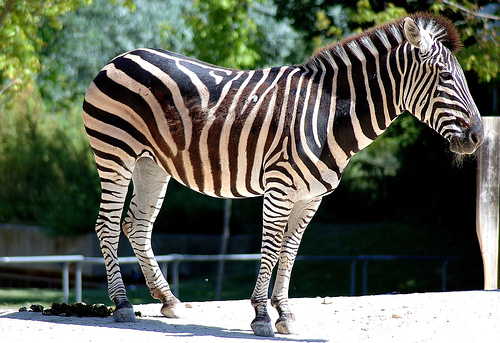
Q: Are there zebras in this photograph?
A: Yes, there is a zebra.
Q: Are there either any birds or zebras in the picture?
A: Yes, there is a zebra.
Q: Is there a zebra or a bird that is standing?
A: Yes, the zebra is standing.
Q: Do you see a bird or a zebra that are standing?
A: Yes, the zebra is standing.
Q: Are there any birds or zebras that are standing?
A: Yes, the zebra is standing.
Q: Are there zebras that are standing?
A: Yes, there is a zebra that is standing.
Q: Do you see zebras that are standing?
A: Yes, there is a zebra that is standing.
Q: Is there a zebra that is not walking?
A: Yes, there is a zebra that is standing.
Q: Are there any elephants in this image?
A: No, there are no elephants.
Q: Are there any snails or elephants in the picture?
A: No, there are no elephants or snails.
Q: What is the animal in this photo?
A: The animal is a zebra.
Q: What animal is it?
A: The animal is a zebra.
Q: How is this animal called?
A: This is a zebra.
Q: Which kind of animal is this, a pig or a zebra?
A: This is a zebra.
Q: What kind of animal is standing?
A: The animal is a zebra.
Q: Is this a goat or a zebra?
A: This is a zebra.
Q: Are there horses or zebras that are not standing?
A: No, there is a zebra but it is standing.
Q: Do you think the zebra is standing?
A: Yes, the zebra is standing.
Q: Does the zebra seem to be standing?
A: Yes, the zebra is standing.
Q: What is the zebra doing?
A: The zebra is standing.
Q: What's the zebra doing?
A: The zebra is standing.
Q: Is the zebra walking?
A: No, the zebra is standing.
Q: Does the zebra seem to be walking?
A: No, the zebra is standing.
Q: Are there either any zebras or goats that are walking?
A: No, there is a zebra but it is standing.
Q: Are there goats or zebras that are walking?
A: No, there is a zebra but it is standing.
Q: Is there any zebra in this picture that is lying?
A: No, there is a zebra but it is standing.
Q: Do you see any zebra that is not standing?
A: No, there is a zebra but it is standing.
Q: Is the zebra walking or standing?
A: The zebra is standing.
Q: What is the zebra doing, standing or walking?
A: The zebra is standing.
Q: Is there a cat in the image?
A: No, there are no cats.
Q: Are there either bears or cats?
A: No, there are no cats or bears.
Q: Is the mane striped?
A: Yes, the mane is striped.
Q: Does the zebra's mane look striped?
A: Yes, the mane is striped.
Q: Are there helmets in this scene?
A: No, there are no helmets.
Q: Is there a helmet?
A: No, there are no helmets.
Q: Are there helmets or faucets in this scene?
A: No, there are no helmets or faucets.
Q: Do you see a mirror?
A: No, there are no mirrors.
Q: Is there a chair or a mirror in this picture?
A: No, there are no mirrors or chairs.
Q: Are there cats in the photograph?
A: No, there are no cats.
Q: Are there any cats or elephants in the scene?
A: No, there are no cats or elephants.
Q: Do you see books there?
A: No, there are no books.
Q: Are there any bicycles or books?
A: No, there are no books or bicycles.